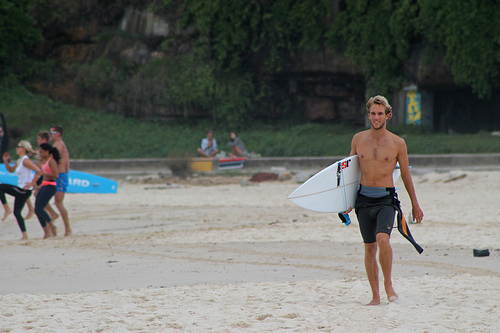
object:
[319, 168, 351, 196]
ground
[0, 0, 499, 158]
landscape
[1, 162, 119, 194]
surfboard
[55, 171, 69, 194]
shorts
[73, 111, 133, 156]
grass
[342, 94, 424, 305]
man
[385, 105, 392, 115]
hair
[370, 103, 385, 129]
man smiling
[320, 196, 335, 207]
ground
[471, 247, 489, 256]
garbage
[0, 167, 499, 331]
beach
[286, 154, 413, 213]
board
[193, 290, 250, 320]
sand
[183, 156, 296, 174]
area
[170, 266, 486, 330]
beach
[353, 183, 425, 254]
wetsuit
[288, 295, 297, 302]
sand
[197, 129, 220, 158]
people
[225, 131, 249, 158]
people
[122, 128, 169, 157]
grass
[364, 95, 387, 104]
hair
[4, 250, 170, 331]
beach